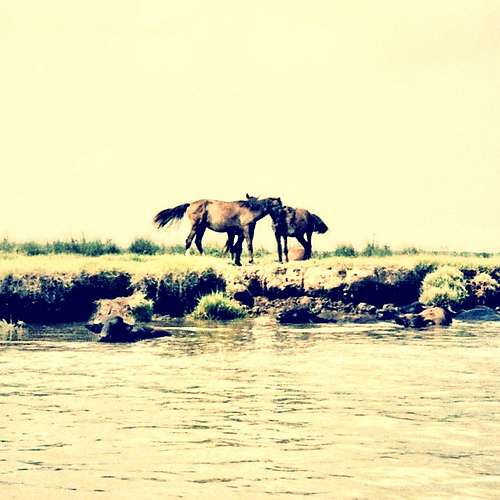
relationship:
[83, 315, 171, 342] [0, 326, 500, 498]
animal swimming in water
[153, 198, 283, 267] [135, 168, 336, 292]
horse has legs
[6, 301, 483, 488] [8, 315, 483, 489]
water in river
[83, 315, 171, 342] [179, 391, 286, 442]
animal in water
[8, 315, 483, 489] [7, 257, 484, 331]
river has bank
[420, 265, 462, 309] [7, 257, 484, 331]
grass on bank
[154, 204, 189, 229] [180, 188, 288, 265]
tail of horse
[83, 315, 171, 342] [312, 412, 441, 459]
animal wading water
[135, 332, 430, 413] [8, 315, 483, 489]
water flowing into river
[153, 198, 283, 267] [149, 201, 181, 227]
horse has tail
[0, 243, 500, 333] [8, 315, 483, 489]
bank of river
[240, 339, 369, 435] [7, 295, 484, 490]
water in river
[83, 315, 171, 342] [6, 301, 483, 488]
animal in water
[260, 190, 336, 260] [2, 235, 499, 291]
horse in field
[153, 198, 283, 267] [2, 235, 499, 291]
horse in field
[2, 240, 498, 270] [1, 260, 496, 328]
grass near bank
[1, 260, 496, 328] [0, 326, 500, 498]
bank near water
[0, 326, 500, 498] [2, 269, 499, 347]
water near marsh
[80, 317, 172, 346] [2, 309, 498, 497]
animal swimming in water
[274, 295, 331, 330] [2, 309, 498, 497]
swimming cow swimming in water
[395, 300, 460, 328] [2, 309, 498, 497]
swimming cow swimming in water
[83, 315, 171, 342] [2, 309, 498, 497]
animal swimming in water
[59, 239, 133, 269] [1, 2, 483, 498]
grass shown in photo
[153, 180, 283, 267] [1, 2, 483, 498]
horse shown in photo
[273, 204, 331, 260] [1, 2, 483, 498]
horse shown in photo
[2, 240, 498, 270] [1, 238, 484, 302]
grass growing in field